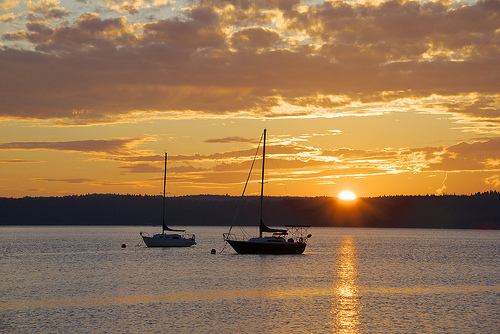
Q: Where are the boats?
A: Water.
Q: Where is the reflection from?
A: Sun.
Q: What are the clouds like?
A: Fluffy.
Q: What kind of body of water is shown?
A: Lake.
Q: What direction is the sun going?
A: South.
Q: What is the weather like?
A: Sunny.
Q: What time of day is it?
A: Sundown.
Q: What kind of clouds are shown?
A: Nimbus.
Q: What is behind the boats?
A: Mountains.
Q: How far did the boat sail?
A: 29 miles from shore.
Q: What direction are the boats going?
A: North.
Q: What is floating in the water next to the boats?
A: Buoys.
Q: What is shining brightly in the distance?
A: The sun.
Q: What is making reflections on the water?
A: The sun.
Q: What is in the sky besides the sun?
A: Clouds.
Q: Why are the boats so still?
A: Anchored down.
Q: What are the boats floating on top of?
A: Water.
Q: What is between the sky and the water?
A: Trees.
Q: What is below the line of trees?
A: Water.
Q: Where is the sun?
A: Above the trees.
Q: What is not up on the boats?
A: Sails.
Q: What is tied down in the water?
A: Boats.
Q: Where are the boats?
A: Water.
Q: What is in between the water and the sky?
A: Trees.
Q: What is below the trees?
A: Water.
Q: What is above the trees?
A: Sky.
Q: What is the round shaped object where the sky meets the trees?
A: Sun.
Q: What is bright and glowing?
A: Sun.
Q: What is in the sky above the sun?
A: Clouds.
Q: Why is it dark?
A: Sunset.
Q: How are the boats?
A: Close.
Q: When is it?
A: Evening.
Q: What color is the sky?
A: Yellow.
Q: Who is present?
A: Nobody.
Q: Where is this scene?
A: On the bay.